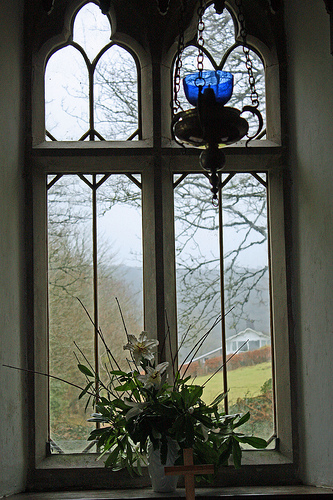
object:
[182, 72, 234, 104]
glass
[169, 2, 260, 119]
chains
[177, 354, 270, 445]
hill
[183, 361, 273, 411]
grass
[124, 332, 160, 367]
flowers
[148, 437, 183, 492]
vase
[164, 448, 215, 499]
cross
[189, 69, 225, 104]
candle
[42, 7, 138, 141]
window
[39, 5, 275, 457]
window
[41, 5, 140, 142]
top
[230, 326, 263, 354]
house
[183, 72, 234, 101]
lamp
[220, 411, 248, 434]
leaf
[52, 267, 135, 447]
trees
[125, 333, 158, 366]
lily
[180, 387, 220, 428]
leaves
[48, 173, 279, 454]
background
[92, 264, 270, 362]
mountains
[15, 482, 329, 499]
lidge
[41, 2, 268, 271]
sky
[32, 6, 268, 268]
clouds